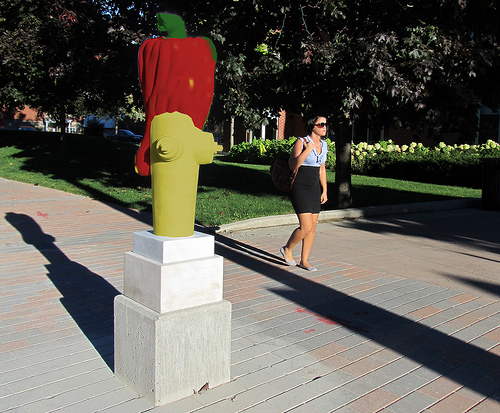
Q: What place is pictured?
A: It is a walkway.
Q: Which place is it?
A: It is a walkway.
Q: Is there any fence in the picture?
A: No, there are no fences.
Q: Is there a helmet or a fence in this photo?
A: No, there are no fences or helmets.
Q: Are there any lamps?
A: No, there are no lamps.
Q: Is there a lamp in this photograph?
A: No, there are no lamps.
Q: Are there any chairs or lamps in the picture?
A: No, there are no lamps or chairs.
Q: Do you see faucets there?
A: No, there are no faucets.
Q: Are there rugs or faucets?
A: No, there are no faucets or rugs.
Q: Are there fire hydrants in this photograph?
A: Yes, there is a fire hydrant.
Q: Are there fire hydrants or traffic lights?
A: Yes, there is a fire hydrant.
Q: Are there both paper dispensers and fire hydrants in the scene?
A: No, there is a fire hydrant but no paper dispensers.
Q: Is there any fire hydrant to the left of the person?
A: Yes, there is a fire hydrant to the left of the person.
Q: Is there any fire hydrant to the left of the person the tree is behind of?
A: Yes, there is a fire hydrant to the left of the person.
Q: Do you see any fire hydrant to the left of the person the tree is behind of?
A: Yes, there is a fire hydrant to the left of the person.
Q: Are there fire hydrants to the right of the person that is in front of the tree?
A: No, the fire hydrant is to the left of the person.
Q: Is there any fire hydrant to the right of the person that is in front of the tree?
A: No, the fire hydrant is to the left of the person.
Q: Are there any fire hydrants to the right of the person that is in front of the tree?
A: No, the fire hydrant is to the left of the person.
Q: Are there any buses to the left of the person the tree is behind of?
A: No, there is a fire hydrant to the left of the person.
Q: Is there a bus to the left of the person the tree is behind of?
A: No, there is a fire hydrant to the left of the person.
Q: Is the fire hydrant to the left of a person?
A: Yes, the fire hydrant is to the left of a person.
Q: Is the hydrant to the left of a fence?
A: No, the hydrant is to the left of a person.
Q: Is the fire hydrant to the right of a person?
A: No, the fire hydrant is to the left of a person.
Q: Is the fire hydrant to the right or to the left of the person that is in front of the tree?
A: The fire hydrant is to the left of the person.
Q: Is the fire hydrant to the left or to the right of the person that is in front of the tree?
A: The fire hydrant is to the left of the person.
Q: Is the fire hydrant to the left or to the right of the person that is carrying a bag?
A: The fire hydrant is to the left of the person.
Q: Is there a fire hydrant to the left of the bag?
A: Yes, there is a fire hydrant to the left of the bag.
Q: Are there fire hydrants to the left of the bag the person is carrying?
A: Yes, there is a fire hydrant to the left of the bag.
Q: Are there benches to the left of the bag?
A: No, there is a fire hydrant to the left of the bag.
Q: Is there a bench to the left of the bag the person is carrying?
A: No, there is a fire hydrant to the left of the bag.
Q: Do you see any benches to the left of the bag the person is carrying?
A: No, there is a fire hydrant to the left of the bag.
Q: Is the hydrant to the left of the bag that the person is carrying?
A: Yes, the hydrant is to the left of the bag.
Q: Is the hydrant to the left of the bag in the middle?
A: Yes, the hydrant is to the left of the bag.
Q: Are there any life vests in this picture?
A: No, there are no life vests.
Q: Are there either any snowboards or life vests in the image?
A: No, there are no life vests or snowboards.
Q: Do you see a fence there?
A: No, there are no fences.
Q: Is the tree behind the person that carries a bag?
A: Yes, the tree is behind the person.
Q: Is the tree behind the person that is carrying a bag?
A: Yes, the tree is behind the person.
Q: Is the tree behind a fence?
A: No, the tree is behind the person.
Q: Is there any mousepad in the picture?
A: No, there are no mouse pads.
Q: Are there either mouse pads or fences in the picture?
A: No, there are no mouse pads or fences.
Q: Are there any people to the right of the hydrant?
A: Yes, there is a person to the right of the hydrant.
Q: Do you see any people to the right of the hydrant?
A: Yes, there is a person to the right of the hydrant.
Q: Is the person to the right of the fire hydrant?
A: Yes, the person is to the right of the fire hydrant.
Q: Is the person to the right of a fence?
A: No, the person is to the right of the fire hydrant.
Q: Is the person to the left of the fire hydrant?
A: No, the person is to the right of the fire hydrant.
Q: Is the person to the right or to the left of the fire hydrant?
A: The person is to the right of the fire hydrant.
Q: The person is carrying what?
A: The person is carrying a bag.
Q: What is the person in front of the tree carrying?
A: The person is carrying a bag.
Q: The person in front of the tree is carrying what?
A: The person is carrying a bag.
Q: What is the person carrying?
A: The person is carrying a bag.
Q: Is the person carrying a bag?
A: Yes, the person is carrying a bag.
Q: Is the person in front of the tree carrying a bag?
A: Yes, the person is carrying a bag.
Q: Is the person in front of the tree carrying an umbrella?
A: No, the person is carrying a bag.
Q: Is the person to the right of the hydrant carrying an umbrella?
A: No, the person is carrying a bag.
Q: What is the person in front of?
A: The person is in front of the tree.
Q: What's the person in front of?
A: The person is in front of the tree.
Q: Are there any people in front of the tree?
A: Yes, there is a person in front of the tree.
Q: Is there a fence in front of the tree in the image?
A: No, there is a person in front of the tree.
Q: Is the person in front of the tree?
A: Yes, the person is in front of the tree.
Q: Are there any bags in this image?
A: Yes, there is a bag.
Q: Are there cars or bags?
A: Yes, there is a bag.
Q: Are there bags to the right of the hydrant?
A: Yes, there is a bag to the right of the hydrant.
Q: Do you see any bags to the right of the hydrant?
A: Yes, there is a bag to the right of the hydrant.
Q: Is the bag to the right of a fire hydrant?
A: Yes, the bag is to the right of a fire hydrant.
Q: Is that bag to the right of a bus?
A: No, the bag is to the right of a fire hydrant.